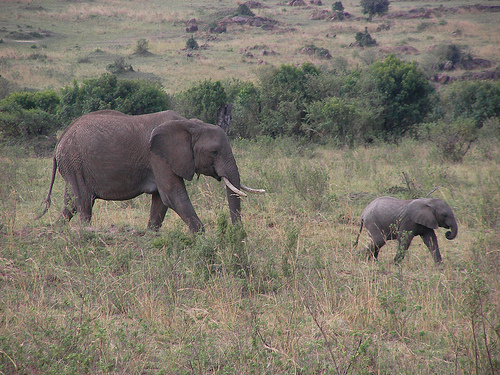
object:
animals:
[32, 114, 459, 264]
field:
[0, 136, 499, 374]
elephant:
[38, 108, 268, 236]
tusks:
[222, 176, 264, 196]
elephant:
[350, 192, 462, 265]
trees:
[0, 59, 499, 161]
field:
[1, 5, 494, 90]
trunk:
[443, 216, 457, 240]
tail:
[37, 152, 58, 216]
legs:
[58, 155, 209, 238]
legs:
[365, 232, 444, 265]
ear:
[146, 125, 195, 183]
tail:
[352, 212, 365, 250]